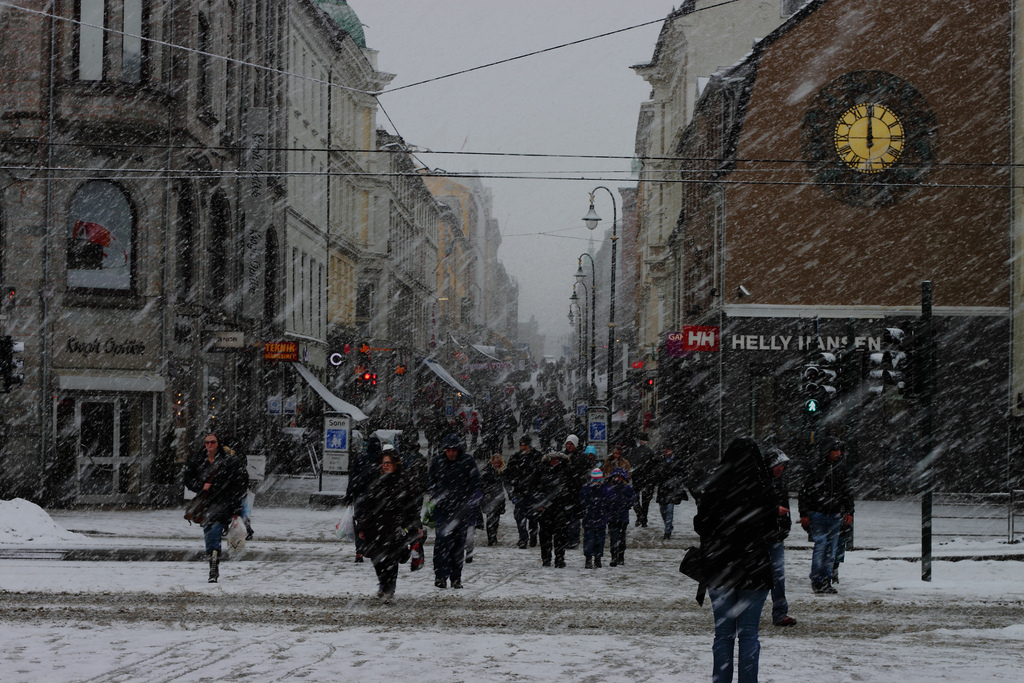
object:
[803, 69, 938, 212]
clock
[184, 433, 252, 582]
people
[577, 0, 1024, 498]
building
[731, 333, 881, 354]
sign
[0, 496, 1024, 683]
snow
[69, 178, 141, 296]
window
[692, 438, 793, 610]
jacket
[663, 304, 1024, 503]
shop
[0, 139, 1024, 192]
wire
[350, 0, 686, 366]
sky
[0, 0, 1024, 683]
snowy day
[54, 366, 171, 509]
doors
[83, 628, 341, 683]
tracks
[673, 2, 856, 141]
roofing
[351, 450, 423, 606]
pedestrians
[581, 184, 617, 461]
lamp post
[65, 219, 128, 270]
decorations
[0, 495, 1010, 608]
drift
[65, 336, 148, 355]
store name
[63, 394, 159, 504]
entryway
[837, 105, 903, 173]
numerals